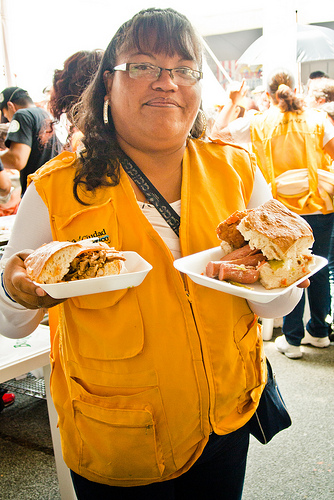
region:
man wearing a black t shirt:
[1, 85, 62, 196]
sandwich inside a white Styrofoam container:
[27, 250, 153, 297]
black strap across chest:
[118, 146, 180, 236]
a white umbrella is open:
[233, 10, 332, 93]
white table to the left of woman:
[0, 322, 88, 499]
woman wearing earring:
[102, 99, 111, 123]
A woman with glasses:
[39, 21, 253, 282]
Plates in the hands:
[3, 228, 313, 311]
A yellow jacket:
[108, 322, 222, 444]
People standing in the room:
[6, 21, 312, 326]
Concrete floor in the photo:
[284, 460, 325, 486]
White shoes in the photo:
[272, 327, 328, 367]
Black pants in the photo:
[167, 448, 251, 497]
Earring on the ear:
[103, 92, 114, 124]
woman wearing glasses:
[115, 43, 202, 83]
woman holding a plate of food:
[15, 234, 149, 294]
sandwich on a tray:
[199, 198, 303, 292]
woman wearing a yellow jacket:
[46, 163, 259, 378]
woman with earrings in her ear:
[99, 93, 111, 123]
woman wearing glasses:
[107, 56, 213, 87]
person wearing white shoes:
[273, 323, 332, 348]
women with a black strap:
[117, 164, 178, 237]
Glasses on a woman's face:
[109, 60, 202, 85]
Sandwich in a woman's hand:
[28, 239, 151, 293]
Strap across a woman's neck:
[120, 154, 182, 231]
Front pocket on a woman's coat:
[65, 375, 167, 477]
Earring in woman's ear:
[99, 98, 110, 122]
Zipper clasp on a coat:
[183, 292, 195, 302]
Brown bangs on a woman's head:
[132, 11, 194, 58]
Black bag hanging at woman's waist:
[252, 364, 293, 446]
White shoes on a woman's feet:
[273, 331, 328, 358]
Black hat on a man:
[0, 86, 22, 106]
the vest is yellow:
[30, 157, 264, 481]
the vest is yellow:
[44, 152, 242, 468]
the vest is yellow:
[39, 146, 256, 465]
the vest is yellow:
[34, 158, 244, 471]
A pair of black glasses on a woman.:
[111, 61, 203, 84]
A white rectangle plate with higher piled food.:
[171, 242, 328, 303]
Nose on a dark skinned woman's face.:
[150, 68, 177, 91]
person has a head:
[100, 13, 201, 143]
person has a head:
[269, 72, 297, 103]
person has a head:
[315, 77, 333, 104]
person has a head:
[0, 88, 35, 119]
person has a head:
[51, 51, 103, 116]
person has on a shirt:
[26, 137, 273, 486]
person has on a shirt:
[252, 107, 333, 214]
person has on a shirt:
[5, 110, 59, 198]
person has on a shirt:
[321, 102, 333, 127]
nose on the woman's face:
[156, 76, 175, 91]